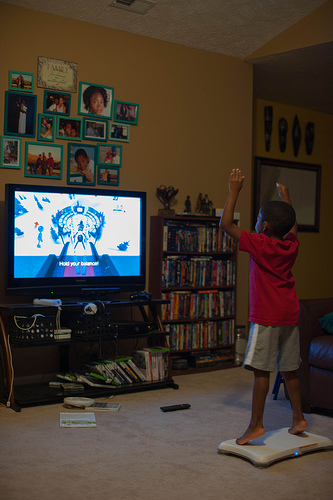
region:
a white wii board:
[215, 407, 331, 485]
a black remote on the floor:
[147, 383, 218, 440]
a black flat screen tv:
[3, 174, 160, 325]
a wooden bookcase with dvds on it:
[142, 187, 260, 386]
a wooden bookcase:
[137, 192, 244, 381]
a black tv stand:
[14, 291, 206, 411]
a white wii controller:
[11, 270, 77, 322]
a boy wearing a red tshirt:
[210, 151, 317, 344]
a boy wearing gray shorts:
[230, 191, 312, 390]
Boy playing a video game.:
[215, 158, 316, 447]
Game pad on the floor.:
[210, 419, 332, 472]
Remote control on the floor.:
[156, 399, 195, 414]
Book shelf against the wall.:
[151, 209, 239, 376]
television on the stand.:
[1, 175, 153, 300]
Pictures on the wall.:
[1, 50, 140, 191]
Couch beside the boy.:
[282, 289, 332, 417]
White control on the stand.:
[29, 296, 66, 312]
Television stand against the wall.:
[0, 294, 182, 416]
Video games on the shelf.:
[41, 345, 176, 397]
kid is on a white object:
[219, 404, 310, 467]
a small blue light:
[276, 435, 305, 464]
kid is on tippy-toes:
[230, 414, 315, 451]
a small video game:
[223, 420, 301, 467]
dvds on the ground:
[41, 386, 139, 436]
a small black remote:
[147, 389, 203, 427]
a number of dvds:
[56, 344, 187, 412]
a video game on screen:
[29, 187, 135, 281]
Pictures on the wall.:
[1, 41, 176, 209]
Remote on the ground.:
[152, 394, 211, 426]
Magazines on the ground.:
[55, 388, 139, 450]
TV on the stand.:
[4, 174, 191, 317]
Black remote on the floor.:
[151, 383, 224, 444]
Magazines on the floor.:
[42, 377, 155, 455]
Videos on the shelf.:
[132, 193, 249, 399]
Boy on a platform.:
[185, 375, 330, 479]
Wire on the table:
[14, 295, 94, 349]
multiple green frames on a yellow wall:
[18, 65, 151, 179]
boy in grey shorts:
[259, 208, 308, 382]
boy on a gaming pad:
[235, 155, 297, 497]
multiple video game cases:
[60, 350, 183, 388]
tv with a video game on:
[11, 186, 182, 293]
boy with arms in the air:
[213, 170, 301, 292]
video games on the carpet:
[54, 402, 162, 442]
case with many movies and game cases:
[155, 205, 237, 363]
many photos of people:
[16, 53, 156, 186]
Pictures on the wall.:
[18, 71, 141, 163]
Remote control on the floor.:
[152, 393, 205, 416]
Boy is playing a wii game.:
[226, 178, 317, 444]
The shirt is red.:
[249, 236, 296, 314]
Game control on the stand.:
[125, 286, 157, 304]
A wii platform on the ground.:
[224, 426, 331, 463]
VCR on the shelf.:
[163, 232, 234, 313]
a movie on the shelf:
[187, 299, 198, 308]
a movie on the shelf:
[187, 326, 195, 348]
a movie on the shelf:
[175, 318, 192, 356]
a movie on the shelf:
[216, 322, 228, 350]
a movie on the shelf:
[205, 282, 215, 313]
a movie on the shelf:
[223, 287, 236, 312]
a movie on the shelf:
[180, 287, 205, 321]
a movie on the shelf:
[158, 249, 177, 284]